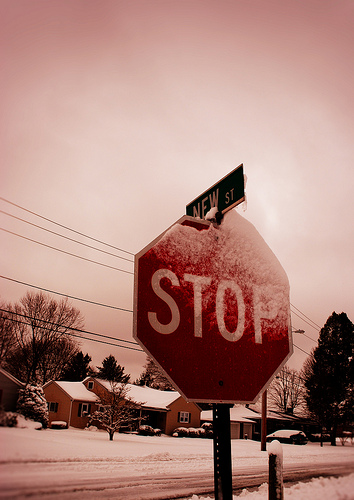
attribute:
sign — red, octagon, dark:
[133, 216, 292, 403]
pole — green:
[215, 402, 236, 498]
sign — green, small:
[185, 163, 245, 213]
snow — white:
[150, 212, 293, 328]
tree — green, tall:
[303, 313, 353, 447]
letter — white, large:
[217, 281, 245, 342]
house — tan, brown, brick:
[43, 374, 203, 437]